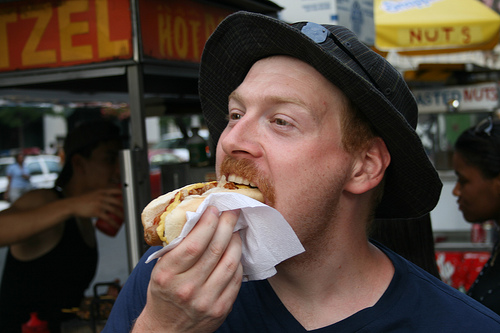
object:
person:
[95, 8, 499, 330]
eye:
[269, 112, 298, 129]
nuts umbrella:
[373, 0, 499, 50]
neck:
[292, 206, 376, 303]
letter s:
[460, 25, 473, 46]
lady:
[0, 99, 152, 315]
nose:
[220, 113, 260, 161]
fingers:
[146, 207, 246, 319]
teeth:
[221, 167, 251, 194]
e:
[58, 3, 91, 63]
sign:
[0, 1, 154, 68]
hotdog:
[138, 167, 267, 246]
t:
[443, 23, 458, 43]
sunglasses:
[291, 22, 374, 88]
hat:
[199, 11, 443, 213]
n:
[408, 26, 420, 42]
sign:
[402, 26, 477, 43]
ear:
[344, 128, 393, 197]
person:
[448, 97, 499, 330]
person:
[0, 107, 147, 330]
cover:
[372, 0, 499, 54]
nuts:
[409, 25, 471, 45]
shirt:
[122, 226, 496, 326]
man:
[100, 10, 491, 333]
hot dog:
[138, 180, 245, 245]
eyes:
[228, 104, 250, 121]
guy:
[105, 8, 498, 330]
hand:
[133, 204, 245, 331]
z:
[15, 9, 59, 67]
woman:
[0, 101, 134, 327]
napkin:
[140, 194, 307, 290]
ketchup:
[129, 191, 196, 231]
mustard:
[151, 191, 202, 240]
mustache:
[220, 157, 272, 189]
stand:
[328, 1, 498, 166]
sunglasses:
[470, 108, 498, 152]